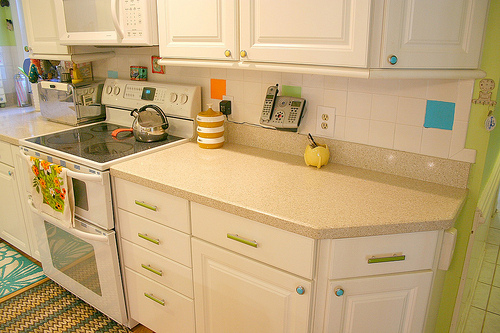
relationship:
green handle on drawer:
[367, 252, 409, 266] [325, 229, 442, 280]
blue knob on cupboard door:
[386, 52, 399, 67] [378, 0, 489, 71]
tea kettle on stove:
[130, 102, 170, 144] [19, 77, 203, 332]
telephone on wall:
[260, 80, 306, 131] [9, 3, 499, 332]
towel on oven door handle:
[26, 153, 77, 229] [18, 149, 104, 187]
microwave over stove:
[56, 1, 160, 50] [19, 77, 203, 332]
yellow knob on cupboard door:
[238, 47, 250, 58] [237, 0, 370, 71]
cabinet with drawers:
[112, 171, 195, 331] [116, 178, 190, 332]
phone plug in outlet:
[220, 100, 231, 117] [222, 92, 236, 120]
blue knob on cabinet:
[334, 287, 345, 297] [321, 270, 432, 332]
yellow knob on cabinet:
[224, 49, 233, 59] [157, 1, 244, 64]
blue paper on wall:
[422, 99, 458, 132] [9, 3, 499, 332]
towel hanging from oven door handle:
[26, 153, 77, 229] [18, 149, 104, 187]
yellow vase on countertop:
[302, 140, 333, 172] [109, 113, 473, 240]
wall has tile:
[9, 3, 499, 332] [90, 49, 479, 164]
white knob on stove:
[104, 81, 113, 97] [19, 77, 203, 332]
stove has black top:
[19, 77, 203, 332] [25, 122, 185, 166]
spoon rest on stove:
[110, 126, 134, 139] [19, 77, 203, 332]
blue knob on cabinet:
[294, 285, 306, 296] [191, 236, 313, 332]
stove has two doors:
[19, 77, 203, 332] [20, 145, 129, 327]